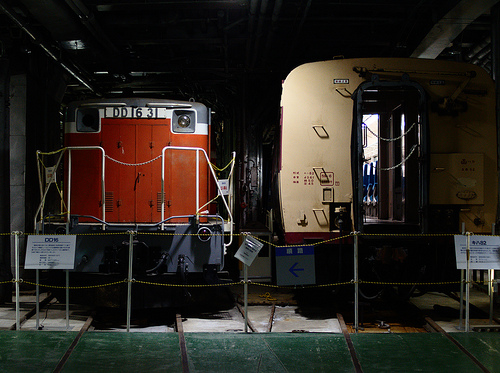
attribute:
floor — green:
[5, 327, 464, 370]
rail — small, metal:
[215, 189, 471, 324]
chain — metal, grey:
[105, 148, 160, 172]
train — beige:
[249, 37, 497, 274]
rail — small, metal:
[173, 315, 190, 372]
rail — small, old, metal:
[23, 187, 497, 342]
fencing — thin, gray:
[2, 219, 498, 339]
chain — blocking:
[371, 134, 458, 196]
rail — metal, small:
[14, 225, 496, 330]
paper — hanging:
[233, 232, 261, 273]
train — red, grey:
[56, 91, 227, 316]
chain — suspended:
[103, 147, 165, 176]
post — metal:
[152, 140, 177, 232]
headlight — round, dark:
[177, 114, 191, 127]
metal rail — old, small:
[314, 302, 382, 369]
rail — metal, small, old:
[235, 225, 258, 340]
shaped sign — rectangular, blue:
[24, 235, 77, 271]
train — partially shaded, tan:
[272, 52, 459, 289]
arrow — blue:
[284, 260, 309, 280]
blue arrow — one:
[276, 252, 317, 287]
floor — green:
[2, 323, 498, 367]